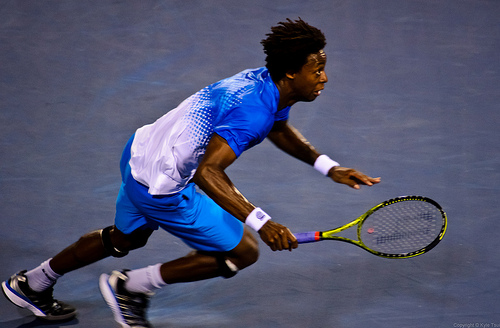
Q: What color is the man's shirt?
A: Blue.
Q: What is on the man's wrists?
A: Wristbands.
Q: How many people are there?
A: One.